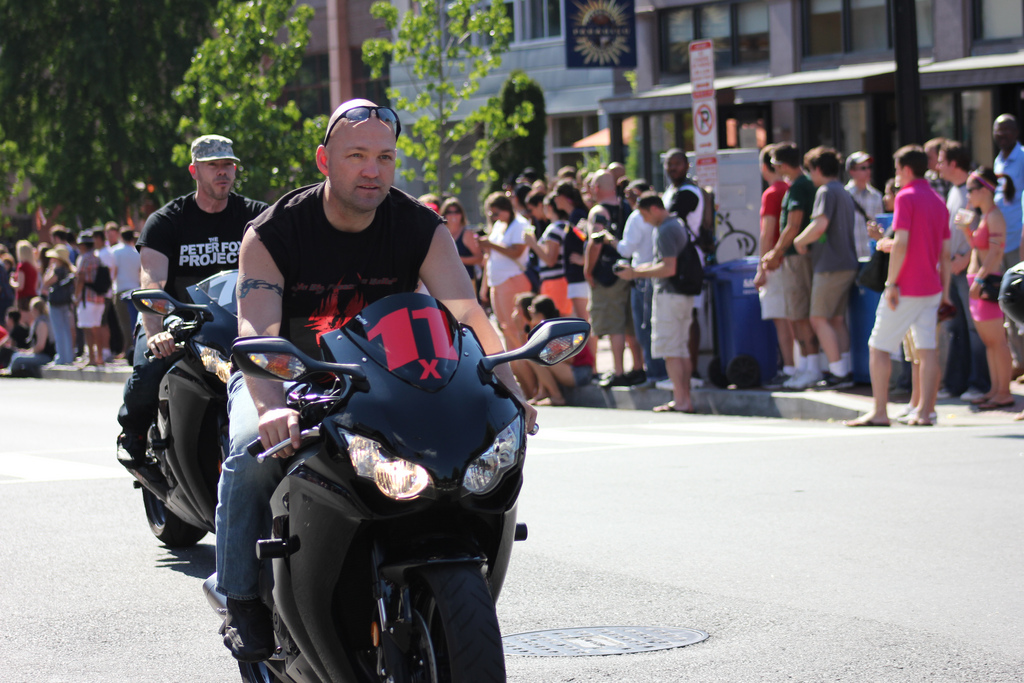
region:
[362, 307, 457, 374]
A red number 11 on a bike.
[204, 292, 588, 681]
A black motorcycle with red 11 on it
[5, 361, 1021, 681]
A grey paved road.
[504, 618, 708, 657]
A round metal manhole.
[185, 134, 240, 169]
A camo hat on a mans head.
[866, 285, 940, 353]
White shorts on a guy in a pink shirt.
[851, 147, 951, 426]
Brown haired man in a pink shirt.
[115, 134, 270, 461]
Man on bike in a hat and black shirt with white letters.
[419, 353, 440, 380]
A red X on a motorcycle.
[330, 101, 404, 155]
sunglasses on a mans head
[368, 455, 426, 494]
a reflective white headlight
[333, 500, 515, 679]
front tire of a motorcycle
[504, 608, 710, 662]
round metal man hole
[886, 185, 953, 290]
pink shirt on a man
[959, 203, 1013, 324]
swimsuit on a woman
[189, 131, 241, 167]
a grey hat on a man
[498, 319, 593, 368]
a mirror and handle bar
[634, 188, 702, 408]
a man looking down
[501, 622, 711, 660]
manhole cover on street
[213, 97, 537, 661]
man in black muscle shirt riding motorcycle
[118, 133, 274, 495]
man in black t-shirt riding motorcycle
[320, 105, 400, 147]
sunglasses on man's head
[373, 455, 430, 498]
headlight on front of motorcycle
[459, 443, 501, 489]
headlight on front of motorcycle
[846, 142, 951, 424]
man in pink shirt and white shorts standing on street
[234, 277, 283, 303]
tattoo on man's arm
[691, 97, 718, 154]
no parking street sign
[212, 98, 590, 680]
a man is riding a motorcycle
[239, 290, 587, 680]
the motorcycle has a red number on the front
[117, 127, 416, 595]
two men are riding motorcycles in the street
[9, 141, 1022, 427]
a crowd of people are curbside on the street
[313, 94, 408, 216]
the man has sunglasses on top of his head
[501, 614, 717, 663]
a manhole cover is in the street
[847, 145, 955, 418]
the boy has a dark pink shirt on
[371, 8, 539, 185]
green leaves on tree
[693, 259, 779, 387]
trash can with wheels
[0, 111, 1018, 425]
crowd of people on sidewalk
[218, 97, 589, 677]
man riding on motorbike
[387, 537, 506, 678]
tire under black fender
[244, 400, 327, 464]
index finger on handle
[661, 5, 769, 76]
three windows with shades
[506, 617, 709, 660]
top of round manhole cover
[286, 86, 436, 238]
sunglasses on the head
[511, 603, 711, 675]
the metal lid of a drain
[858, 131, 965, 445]
man wears a red shirt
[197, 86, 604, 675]
man riding a motorcycle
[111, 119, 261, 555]
man riding a motorcycle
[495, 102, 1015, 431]
a group of people on the sidewalk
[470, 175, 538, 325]
woman wears a white top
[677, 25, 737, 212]
signs on a pole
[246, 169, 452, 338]
the tank is black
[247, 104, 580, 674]
man riding a motorcycle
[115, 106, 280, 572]
man riding a motorcycle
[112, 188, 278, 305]
man wearing a black shirt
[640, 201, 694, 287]
man wearing a gray shirt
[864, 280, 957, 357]
man wearing white shorts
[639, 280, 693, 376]
man wearing white shorts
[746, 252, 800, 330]
man wearing white shorts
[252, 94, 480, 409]
A person on the motorcycle.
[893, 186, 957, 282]
The shirt is pink.